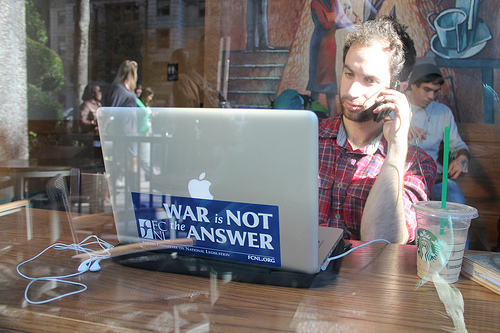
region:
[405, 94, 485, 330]
Green and clear cup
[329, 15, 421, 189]
Man on a cell phone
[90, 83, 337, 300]
Silver colored laptop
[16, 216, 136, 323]
White ear phones on a deak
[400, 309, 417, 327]
Dark brown wood grain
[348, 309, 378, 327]
Dark brown wood grain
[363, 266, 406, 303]
Dark brown wood grain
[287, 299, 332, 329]
Dark brown wood grain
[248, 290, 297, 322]
Dark brown wood grain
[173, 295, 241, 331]
Dark brown wood grain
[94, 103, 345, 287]
Apple laptop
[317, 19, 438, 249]
Person talking on the tell phone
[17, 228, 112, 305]
Set of headphones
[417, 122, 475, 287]
Used Starbucks cup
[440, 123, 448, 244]
Green straw in the Starbucks cup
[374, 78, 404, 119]
Cell phone that's used by the man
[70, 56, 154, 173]
Group of females sitting in the background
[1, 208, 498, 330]
Wooden table beneath the computer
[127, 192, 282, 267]
Blue sticker on top of the laptop cover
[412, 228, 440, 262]
Logo of Starbucks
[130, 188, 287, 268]
sticker on the laptop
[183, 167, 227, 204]
apple logo on the laptop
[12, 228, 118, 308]
two white earbuds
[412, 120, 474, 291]
starbucks clear cup with water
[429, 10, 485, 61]
cup and plate painting on the wall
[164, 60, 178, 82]
restroom sign on the wall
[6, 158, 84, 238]
reflection of a stool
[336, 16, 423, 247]
man talking on a cellphone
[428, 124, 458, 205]
green straw in the cup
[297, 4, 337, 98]
drawing of a woman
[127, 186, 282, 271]
The sticker on the laptop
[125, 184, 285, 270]
the blue anti-war sticker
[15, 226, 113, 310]
white headphones on the desk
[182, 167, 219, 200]
the white apple logo on the computer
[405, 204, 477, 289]
the starbucks cup on the table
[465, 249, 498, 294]
the book on the table top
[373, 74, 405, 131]
the black phone up to the mans ear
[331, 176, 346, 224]
the buttons on the checkered shirt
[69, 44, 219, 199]
the reflection of the people in the window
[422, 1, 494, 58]
the painting of the coffee cup on the shops wall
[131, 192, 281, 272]
sticker on a laptop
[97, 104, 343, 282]
laptop on a counter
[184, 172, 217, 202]
white apple on laptop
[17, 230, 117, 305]
a pair of earbuds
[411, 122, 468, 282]
A plastic Starbucks cup with a lid and a green straw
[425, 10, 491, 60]
a coffee cup and saucer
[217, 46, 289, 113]
stairway painted on the wall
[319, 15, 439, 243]
a beaded balding man on the telephone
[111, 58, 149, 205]
a blonde woman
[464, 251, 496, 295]
a book resting on the table